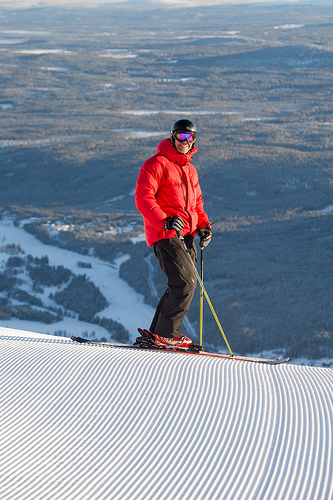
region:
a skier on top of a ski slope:
[70, 107, 294, 368]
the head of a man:
[163, 113, 202, 163]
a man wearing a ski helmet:
[160, 114, 203, 165]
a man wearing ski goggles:
[167, 116, 202, 167]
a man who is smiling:
[164, 107, 210, 169]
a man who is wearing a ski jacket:
[122, 118, 219, 249]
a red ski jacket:
[129, 139, 236, 254]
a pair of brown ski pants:
[142, 234, 219, 341]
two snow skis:
[67, 327, 303, 385]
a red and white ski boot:
[145, 327, 203, 355]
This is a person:
[125, 107, 250, 362]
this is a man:
[138, 101, 242, 368]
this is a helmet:
[171, 116, 189, 134]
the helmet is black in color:
[181, 117, 196, 125]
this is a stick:
[194, 266, 228, 327]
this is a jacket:
[146, 163, 179, 204]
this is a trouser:
[166, 246, 196, 295]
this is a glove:
[171, 207, 185, 236]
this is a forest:
[231, 107, 293, 213]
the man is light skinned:
[174, 142, 192, 151]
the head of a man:
[156, 118, 208, 164]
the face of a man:
[176, 114, 215, 168]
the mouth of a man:
[175, 132, 211, 167]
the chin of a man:
[175, 138, 203, 165]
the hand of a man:
[157, 203, 209, 238]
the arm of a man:
[125, 148, 180, 251]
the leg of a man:
[148, 222, 214, 338]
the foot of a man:
[146, 317, 205, 345]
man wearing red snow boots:
[148, 323, 200, 352]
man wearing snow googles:
[172, 128, 201, 147]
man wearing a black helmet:
[169, 119, 197, 139]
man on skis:
[69, 323, 290, 368]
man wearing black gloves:
[160, 211, 185, 230]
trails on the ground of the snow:
[28, 349, 255, 486]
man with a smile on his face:
[175, 140, 200, 160]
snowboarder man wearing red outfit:
[133, 115, 213, 355]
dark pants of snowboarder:
[145, 234, 198, 351]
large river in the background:
[2, 207, 199, 354]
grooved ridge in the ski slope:
[1, 343, 79, 395]